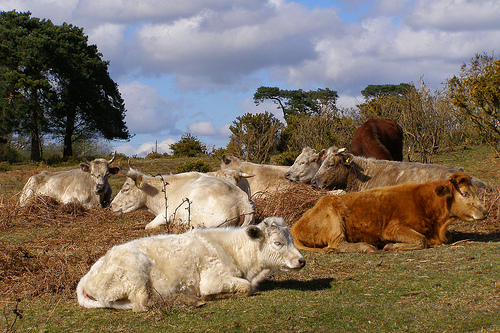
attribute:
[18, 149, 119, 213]
cow — big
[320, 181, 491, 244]
cow — big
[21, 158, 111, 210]
cows — big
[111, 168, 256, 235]
cows — big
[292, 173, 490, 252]
cows — big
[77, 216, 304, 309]
cows — big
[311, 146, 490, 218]
cows — big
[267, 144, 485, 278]
cow — light brown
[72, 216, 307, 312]
cow — big, whitish, white, laying down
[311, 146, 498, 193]
cow — big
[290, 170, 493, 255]
cow — big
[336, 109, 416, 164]
brown cow — standing up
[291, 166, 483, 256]
cow — big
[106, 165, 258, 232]
cow — big, whitish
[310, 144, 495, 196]
cow — whitish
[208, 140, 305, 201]
cow — whitish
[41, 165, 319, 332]
cow — big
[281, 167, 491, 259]
cow — brown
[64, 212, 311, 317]
cow — brown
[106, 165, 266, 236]
cow — brown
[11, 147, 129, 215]
cow — brown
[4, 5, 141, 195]
tree — dark greem, leafy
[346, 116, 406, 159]
brown cow — dark brown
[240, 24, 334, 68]
sky — cloudy blue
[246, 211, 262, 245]
tag — yellow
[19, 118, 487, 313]
cows — big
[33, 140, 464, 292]
cows — big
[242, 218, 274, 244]
ear — cows